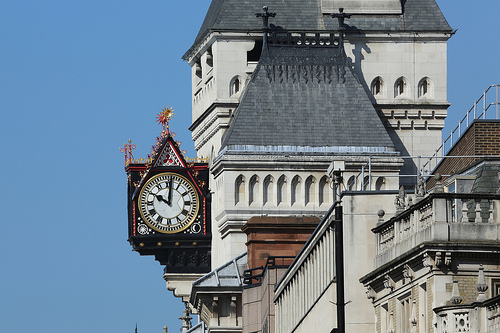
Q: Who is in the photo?
A: Nobody.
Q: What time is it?
A: 10:02.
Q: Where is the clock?
A: On the building.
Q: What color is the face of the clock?
A: White.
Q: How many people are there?
A: None.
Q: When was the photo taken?
A: Daytime.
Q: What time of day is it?
A: Morning.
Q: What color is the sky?
A: Blue.